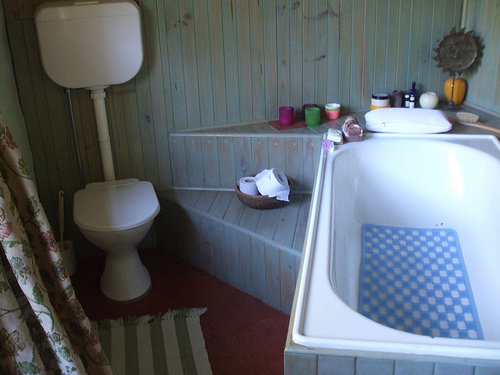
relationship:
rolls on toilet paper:
[237, 168, 291, 203] [239, 168, 291, 204]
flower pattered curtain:
[16, 202, 51, 253] [3, 128, 108, 374]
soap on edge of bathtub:
[323, 124, 343, 145] [291, 132, 500, 361]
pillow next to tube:
[364, 107, 454, 133] [285, 134, 499, 374]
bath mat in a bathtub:
[358, 223, 485, 341] [291, 132, 500, 361]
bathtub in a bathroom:
[291, 132, 500, 361] [1, 0, 496, 373]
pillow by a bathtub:
[358, 104, 458, 133] [285, 127, 485, 353]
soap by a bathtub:
[327, 128, 343, 143] [282, 132, 499, 374]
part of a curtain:
[14, 278, 64, 346] [5, 87, 109, 371]